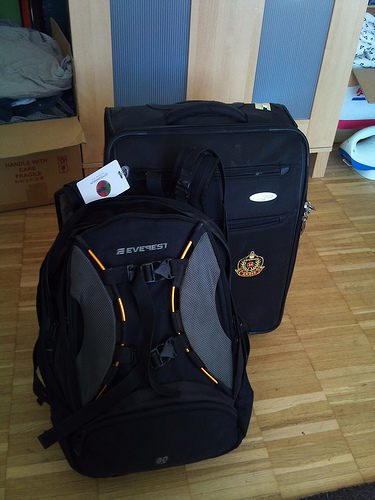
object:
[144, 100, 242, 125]
handle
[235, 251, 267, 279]
emblem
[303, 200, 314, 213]
zipper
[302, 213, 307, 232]
zipper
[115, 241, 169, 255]
name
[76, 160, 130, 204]
tag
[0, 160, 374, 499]
floor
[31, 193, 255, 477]
backpack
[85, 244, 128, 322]
accent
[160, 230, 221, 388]
accent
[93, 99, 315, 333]
suitcase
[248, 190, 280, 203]
decal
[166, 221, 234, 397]
zippered pocket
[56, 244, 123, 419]
zippered pocket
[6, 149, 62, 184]
writing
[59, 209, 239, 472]
panels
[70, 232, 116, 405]
backpack trim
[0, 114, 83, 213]
box